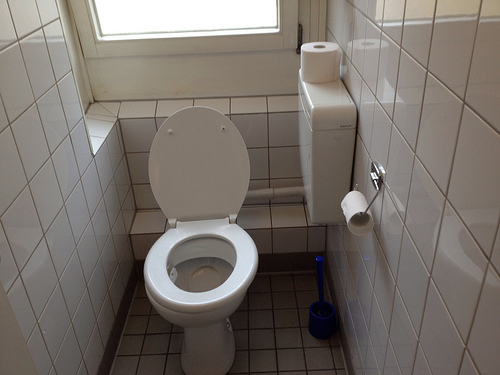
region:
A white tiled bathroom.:
[3, 1, 498, 362]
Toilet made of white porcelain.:
[137, 230, 254, 370]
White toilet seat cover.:
[141, 100, 256, 305]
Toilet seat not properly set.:
[141, 220, 256, 310]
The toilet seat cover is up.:
[141, 105, 251, 220]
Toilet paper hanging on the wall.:
[336, 157, 382, 242]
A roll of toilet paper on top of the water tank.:
[295, 31, 345, 86]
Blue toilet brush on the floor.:
[305, 252, 340, 337]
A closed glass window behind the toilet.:
[65, 0, 300, 60]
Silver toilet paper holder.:
[351, 160, 387, 220]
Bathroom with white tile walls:
[0, 0, 497, 374]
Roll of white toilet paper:
[336, 189, 375, 238]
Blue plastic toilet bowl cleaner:
[304, 252, 340, 344]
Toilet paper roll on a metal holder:
[337, 157, 387, 239]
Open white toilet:
[137, 107, 257, 374]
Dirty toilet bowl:
[170, 256, 232, 298]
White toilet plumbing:
[240, 183, 304, 205]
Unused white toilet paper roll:
[298, 38, 343, 87]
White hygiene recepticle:
[295, 65, 358, 227]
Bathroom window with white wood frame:
[68, 0, 300, 61]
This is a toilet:
[54, 47, 466, 372]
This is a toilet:
[15, 51, 495, 362]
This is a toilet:
[13, 32, 498, 367]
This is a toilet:
[14, 39, 499, 361]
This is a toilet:
[5, 23, 495, 363]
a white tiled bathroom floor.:
[247, 320, 301, 373]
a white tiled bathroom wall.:
[0, 172, 95, 287]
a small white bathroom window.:
[67, 0, 301, 47]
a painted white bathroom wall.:
[94, 41, 293, 93]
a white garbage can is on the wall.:
[297, 79, 365, 226]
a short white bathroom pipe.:
[249, 181, 306, 203]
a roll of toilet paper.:
[295, 37, 346, 85]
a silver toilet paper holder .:
[337, 159, 389, 237]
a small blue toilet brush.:
[303, 250, 344, 342]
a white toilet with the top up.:
[128, 103, 265, 373]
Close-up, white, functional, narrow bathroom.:
[7, 1, 499, 370]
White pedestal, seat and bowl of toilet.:
[153, 222, 253, 368]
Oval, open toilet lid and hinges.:
[155, 111, 249, 243]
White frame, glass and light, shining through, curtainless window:
[77, 3, 311, 49]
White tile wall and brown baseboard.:
[9, 29, 119, 373]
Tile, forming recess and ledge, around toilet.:
[102, 109, 299, 243]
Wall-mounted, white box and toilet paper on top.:
[297, 31, 384, 170]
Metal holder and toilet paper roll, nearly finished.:
[338, 159, 394, 233]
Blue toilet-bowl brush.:
[303, 253, 347, 340]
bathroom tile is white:
[232, 112, 269, 146]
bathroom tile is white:
[265, 112, 298, 147]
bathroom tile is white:
[266, 144, 301, 178]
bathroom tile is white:
[121, 115, 158, 151]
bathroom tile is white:
[157, 99, 193, 116]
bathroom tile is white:
[121, 98, 157, 116]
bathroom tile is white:
[194, 95, 230, 115]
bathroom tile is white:
[231, 94, 268, 114]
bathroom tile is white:
[264, 91, 299, 111]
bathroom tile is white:
[269, 114, 299, 146]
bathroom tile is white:
[127, 149, 153, 180]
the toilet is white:
[144, 221, 269, 343]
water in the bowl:
[171, 241, 233, 290]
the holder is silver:
[365, 155, 408, 221]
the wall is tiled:
[3, 147, 113, 304]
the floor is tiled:
[261, 270, 351, 365]